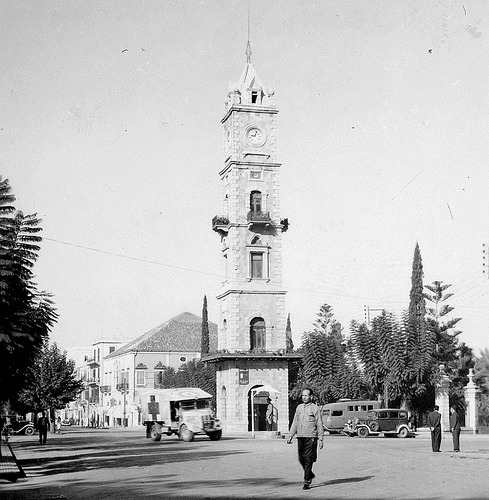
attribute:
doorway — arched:
[247, 384, 272, 432]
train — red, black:
[324, 388, 384, 438]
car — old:
[342, 406, 414, 437]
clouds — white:
[19, 181, 486, 299]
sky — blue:
[2, 3, 486, 335]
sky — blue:
[33, 29, 487, 318]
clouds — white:
[222, 37, 368, 171]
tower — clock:
[203, 16, 307, 441]